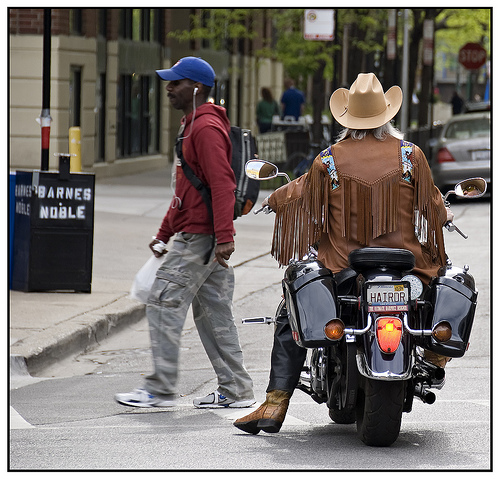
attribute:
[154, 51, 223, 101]
cap — BLUE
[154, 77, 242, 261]
man — walking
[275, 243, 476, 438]
motorcycle — black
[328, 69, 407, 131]
hat — large, brown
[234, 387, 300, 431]
boot — brown, tan, cowboy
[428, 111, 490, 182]
car — parked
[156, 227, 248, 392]
pants — camo, cargo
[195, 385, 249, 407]
shoes — nike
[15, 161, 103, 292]
dispenser — black, barnes, noble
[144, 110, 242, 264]
jacket — RED